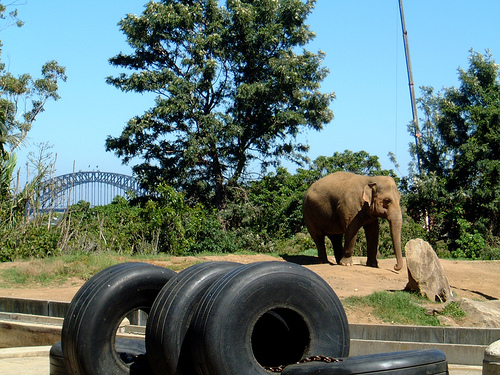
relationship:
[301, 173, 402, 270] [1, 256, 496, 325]
elephant in dirt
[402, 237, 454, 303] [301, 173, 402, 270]
stump in front of elephant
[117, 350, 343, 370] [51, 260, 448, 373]
chain on tires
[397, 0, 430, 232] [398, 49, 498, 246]
pole behind trees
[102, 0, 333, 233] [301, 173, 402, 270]
tree behind elephant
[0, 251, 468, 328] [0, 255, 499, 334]
grass on ground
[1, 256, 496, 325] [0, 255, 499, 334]
dirt on ground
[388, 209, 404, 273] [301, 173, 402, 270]
trunk on elephant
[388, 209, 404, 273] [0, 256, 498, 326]
trunk on ground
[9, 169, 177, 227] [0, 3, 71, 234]
bridge behind tree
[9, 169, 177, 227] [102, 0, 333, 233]
bridge behind tree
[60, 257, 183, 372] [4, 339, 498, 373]
tires on ground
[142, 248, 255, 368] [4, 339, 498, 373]
tires on ground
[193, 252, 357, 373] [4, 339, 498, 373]
tires on ground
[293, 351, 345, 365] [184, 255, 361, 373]
chain on tire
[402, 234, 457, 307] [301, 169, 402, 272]
rock in front of elephant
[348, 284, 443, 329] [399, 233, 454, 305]
grass next to rock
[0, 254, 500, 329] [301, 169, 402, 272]
dirt under elephant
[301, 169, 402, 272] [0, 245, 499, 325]
elephant standing on dirt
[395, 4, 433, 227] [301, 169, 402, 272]
pole behind elephant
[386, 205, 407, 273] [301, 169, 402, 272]
trunk of elephant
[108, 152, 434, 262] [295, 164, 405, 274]
bushes behind elephant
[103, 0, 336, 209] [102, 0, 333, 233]
leaves on tree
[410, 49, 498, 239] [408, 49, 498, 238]
leaves on tree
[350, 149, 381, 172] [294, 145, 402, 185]
leaves on tree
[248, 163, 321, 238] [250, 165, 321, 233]
leaves on tree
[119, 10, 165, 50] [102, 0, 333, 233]
leaves on tree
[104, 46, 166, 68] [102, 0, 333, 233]
leaves on tree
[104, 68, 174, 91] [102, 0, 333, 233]
leaves on tree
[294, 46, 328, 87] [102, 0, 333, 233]
leaves on tree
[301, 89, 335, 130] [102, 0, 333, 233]
leaves on tree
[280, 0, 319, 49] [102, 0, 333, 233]
leaves on tree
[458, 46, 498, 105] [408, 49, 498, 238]
leaves on tree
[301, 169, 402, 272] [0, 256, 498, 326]
elephant on ground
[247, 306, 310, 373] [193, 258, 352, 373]
hole in middle of tires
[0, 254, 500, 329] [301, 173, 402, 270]
dirt in front of elephant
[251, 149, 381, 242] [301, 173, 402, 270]
tree behind elephant